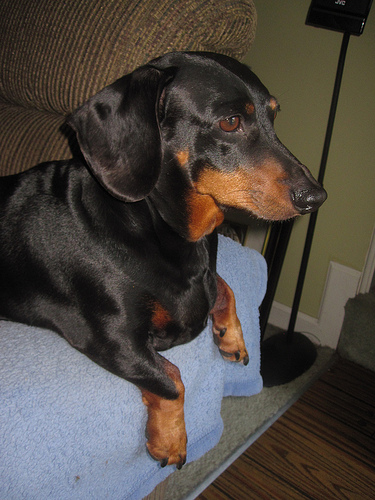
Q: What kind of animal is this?
A: Dog.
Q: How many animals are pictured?
A: One.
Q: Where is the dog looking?
A: Away from the camera.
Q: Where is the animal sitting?
A: On the furniture.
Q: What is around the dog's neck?
A: Nothing.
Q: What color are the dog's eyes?
A: Brown.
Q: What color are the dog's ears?
A: Black.